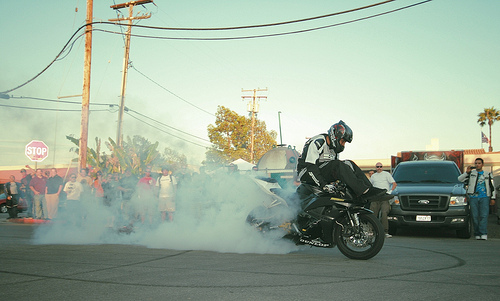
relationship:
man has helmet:
[333, 120, 352, 158] [323, 113, 357, 155]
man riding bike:
[333, 120, 352, 158] [234, 153, 395, 273]